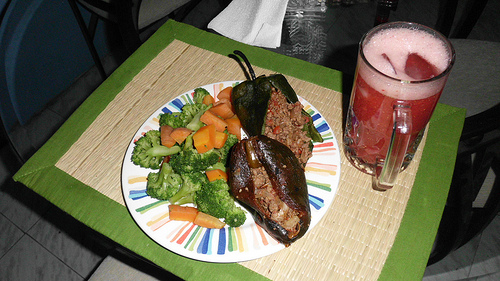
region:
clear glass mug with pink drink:
[345, 15, 456, 182]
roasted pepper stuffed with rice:
[215, 136, 311, 246]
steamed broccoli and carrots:
[131, 87, 248, 227]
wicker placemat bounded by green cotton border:
[16, 15, 486, 275]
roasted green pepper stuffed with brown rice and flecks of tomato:
[229, 40, 324, 162]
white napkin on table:
[208, 0, 305, 51]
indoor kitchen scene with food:
[8, 0, 497, 277]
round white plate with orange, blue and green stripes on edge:
[111, 65, 351, 264]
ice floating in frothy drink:
[367, 46, 438, 82]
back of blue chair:
[5, 8, 132, 132]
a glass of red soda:
[344, 17, 456, 189]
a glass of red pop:
[342, 18, 455, 204]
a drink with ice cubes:
[346, 22, 457, 194]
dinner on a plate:
[119, 46, 346, 266]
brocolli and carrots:
[131, 84, 236, 232]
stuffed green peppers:
[230, 49, 321, 246]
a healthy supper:
[131, 25, 460, 241]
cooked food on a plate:
[122, 48, 342, 265]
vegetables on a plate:
[124, 77, 244, 265]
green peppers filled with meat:
[229, 47, 319, 249]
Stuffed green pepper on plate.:
[238, 53, 306, 139]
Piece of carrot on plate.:
[196, 207, 224, 232]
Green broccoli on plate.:
[211, 198, 248, 225]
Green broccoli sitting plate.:
[177, 173, 203, 205]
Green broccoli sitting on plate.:
[150, 168, 179, 204]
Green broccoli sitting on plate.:
[138, 133, 165, 164]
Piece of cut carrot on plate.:
[158, 118, 188, 151]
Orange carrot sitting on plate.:
[197, 121, 211, 145]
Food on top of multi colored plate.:
[138, 70, 314, 247]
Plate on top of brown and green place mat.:
[129, 72, 336, 267]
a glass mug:
[341, 19, 456, 190]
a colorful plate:
[119, 76, 337, 261]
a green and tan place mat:
[9, 15, 465, 279]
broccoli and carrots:
[133, 84, 244, 225]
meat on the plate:
[229, 135, 309, 242]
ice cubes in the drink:
[379, 48, 437, 79]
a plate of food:
[119, 73, 338, 263]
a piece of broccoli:
[145, 163, 185, 200]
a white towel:
[205, 0, 288, 48]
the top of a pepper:
[228, 49, 300, 134]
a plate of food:
[76, 41, 453, 278]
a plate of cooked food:
[122, 28, 397, 274]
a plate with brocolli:
[119, 38, 368, 275]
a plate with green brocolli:
[112, 23, 387, 277]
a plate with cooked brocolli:
[86, 81, 393, 280]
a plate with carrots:
[122, 63, 396, 277]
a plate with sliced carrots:
[115, 58, 362, 243]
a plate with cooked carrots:
[76, 51, 418, 275]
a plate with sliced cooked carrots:
[100, 66, 381, 274]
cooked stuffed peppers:
[162, 39, 357, 219]